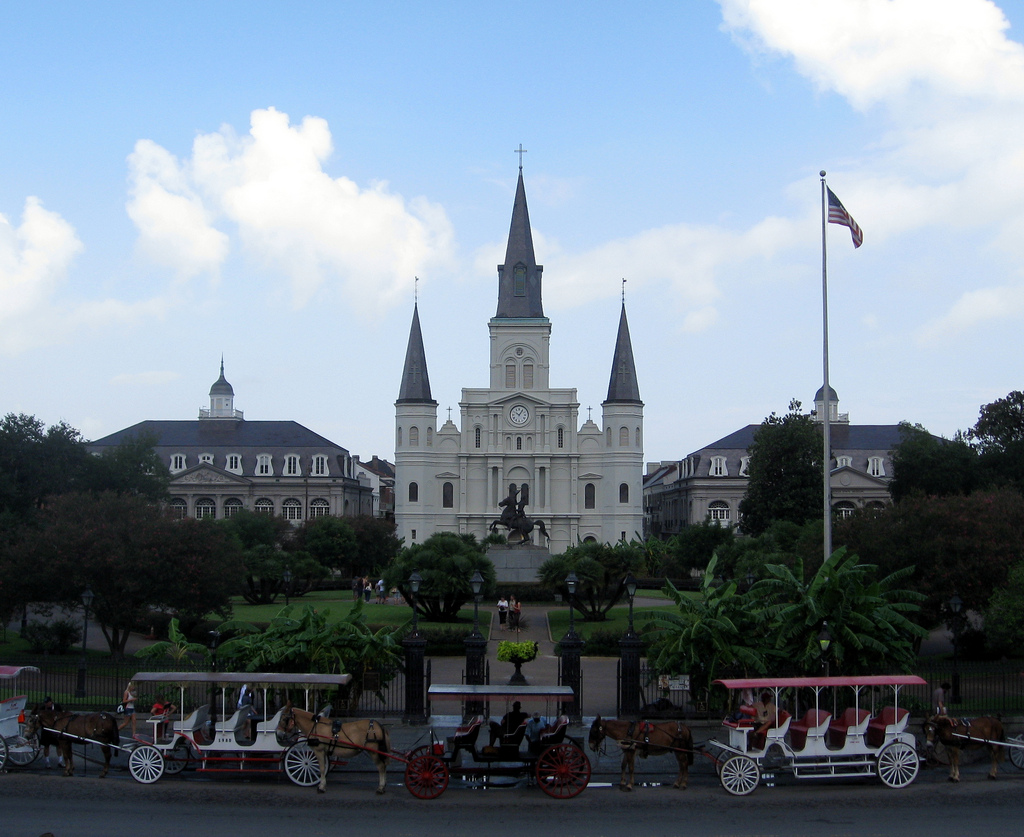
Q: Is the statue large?
A: Yes, the statue is large.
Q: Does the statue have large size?
A: Yes, the statue is large.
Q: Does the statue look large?
A: Yes, the statue is large.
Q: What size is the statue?
A: The statue is large.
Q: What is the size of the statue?
A: The statue is large.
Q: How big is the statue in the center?
A: The statue is large.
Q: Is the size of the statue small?
A: No, the statue is large.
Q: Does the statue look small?
A: No, the statue is large.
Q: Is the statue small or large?
A: The statue is large.